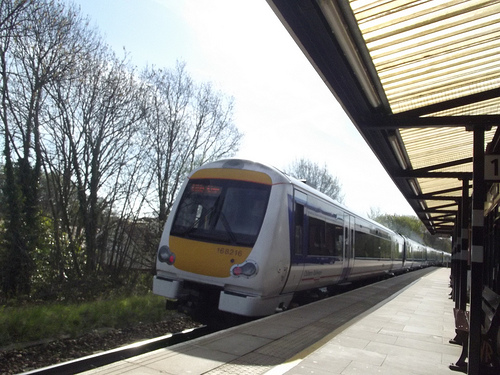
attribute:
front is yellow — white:
[153, 156, 283, 310]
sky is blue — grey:
[3, 1, 412, 222]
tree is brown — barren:
[145, 67, 230, 266]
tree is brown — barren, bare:
[62, 57, 123, 274]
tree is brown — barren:
[12, 6, 59, 277]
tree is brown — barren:
[293, 157, 339, 195]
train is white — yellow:
[150, 158, 449, 313]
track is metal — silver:
[5, 322, 214, 374]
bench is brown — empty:
[455, 283, 498, 370]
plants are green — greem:
[4, 162, 158, 300]